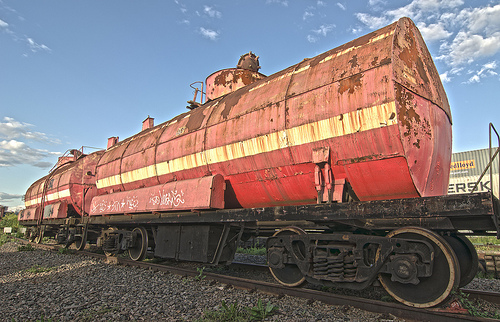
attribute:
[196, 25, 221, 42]
cloud — white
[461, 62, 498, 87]
cloud — white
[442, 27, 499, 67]
cloud — white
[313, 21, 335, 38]
cloud — white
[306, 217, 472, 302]
wheel — large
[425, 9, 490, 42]
clouds — light and fluffy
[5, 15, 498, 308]
car — red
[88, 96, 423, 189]
stripes — yellow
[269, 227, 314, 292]
car wheel — large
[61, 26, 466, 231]
tanker — red and yellow, long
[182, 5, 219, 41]
cloud — white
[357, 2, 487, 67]
cloud — white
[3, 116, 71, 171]
cloud — white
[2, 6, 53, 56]
cloud — white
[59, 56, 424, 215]
train — red and yellow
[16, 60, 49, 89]
clouds — white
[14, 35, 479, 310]
car — large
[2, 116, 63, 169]
clouds — white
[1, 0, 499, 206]
sky — blue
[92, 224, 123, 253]
wheel — large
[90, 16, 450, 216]
tanker — not usable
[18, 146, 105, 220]
tanker — not usable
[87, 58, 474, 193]
train — red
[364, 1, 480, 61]
cloud — white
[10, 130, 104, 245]
tanker — red and yellow, long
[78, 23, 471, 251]
car — rusty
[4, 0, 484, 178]
sky — blue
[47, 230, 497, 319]
tracks — train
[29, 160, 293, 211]
carts — materials